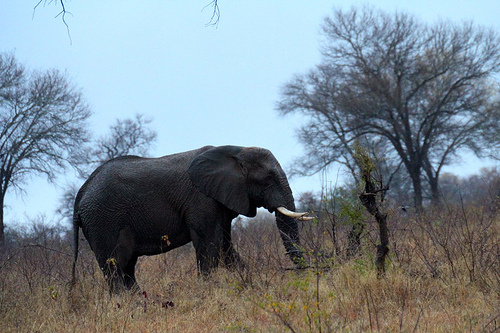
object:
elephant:
[64, 144, 316, 300]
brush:
[300, 197, 498, 259]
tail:
[63, 219, 79, 298]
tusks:
[276, 206, 309, 218]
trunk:
[272, 197, 313, 269]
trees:
[276, 8, 500, 216]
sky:
[10, 8, 297, 145]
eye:
[266, 170, 278, 179]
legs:
[187, 226, 224, 281]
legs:
[86, 232, 137, 297]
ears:
[186, 144, 254, 218]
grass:
[0, 274, 152, 332]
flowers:
[288, 305, 292, 310]